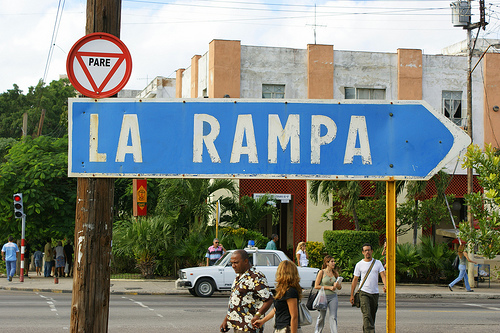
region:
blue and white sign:
[66, 102, 456, 182]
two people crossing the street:
[306, 241, 391, 332]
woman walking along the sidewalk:
[447, 238, 477, 289]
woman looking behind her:
[250, 253, 318, 332]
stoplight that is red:
[10, 193, 30, 223]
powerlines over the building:
[180, 1, 496, 56]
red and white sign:
[53, 25, 139, 102]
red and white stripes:
[14, 236, 29, 283]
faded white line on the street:
[123, 291, 166, 331]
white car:
[176, 243, 337, 304]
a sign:
[58, 62, 492, 275]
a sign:
[164, 35, 353, 226]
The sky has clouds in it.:
[130, 0, 277, 32]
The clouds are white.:
[140, 0, 264, 33]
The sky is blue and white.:
[141, 1, 253, 23]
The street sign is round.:
[60, 28, 135, 98]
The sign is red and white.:
[59, 28, 139, 95]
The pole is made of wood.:
[60, 0, 130, 332]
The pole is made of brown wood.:
[59, 0, 124, 332]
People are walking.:
[0, 226, 89, 303]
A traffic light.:
[3, 185, 38, 280]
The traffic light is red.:
[8, 182, 33, 232]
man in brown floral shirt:
[208, 246, 278, 332]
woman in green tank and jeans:
[308, 248, 341, 324]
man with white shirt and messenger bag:
[348, 235, 381, 328]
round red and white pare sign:
[61, 26, 135, 95]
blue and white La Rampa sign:
[62, 91, 484, 191]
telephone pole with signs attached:
[50, 10, 450, 325]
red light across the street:
[5, 185, 30, 280]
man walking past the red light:
[1, 235, 21, 290]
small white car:
[175, 237, 337, 307]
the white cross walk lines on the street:
[35, 280, 172, 327]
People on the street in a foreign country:
[40, 57, 488, 328]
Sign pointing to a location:
[58, 90, 476, 190]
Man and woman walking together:
[220, 245, 305, 330]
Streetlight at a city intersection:
[7, 190, 27, 221]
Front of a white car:
[170, 265, 223, 296]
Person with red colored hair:
[271, 257, 301, 300]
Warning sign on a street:
[63, 25, 139, 100]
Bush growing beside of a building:
[120, 203, 175, 286]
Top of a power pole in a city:
[440, 0, 497, 45]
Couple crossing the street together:
[311, 245, 387, 331]